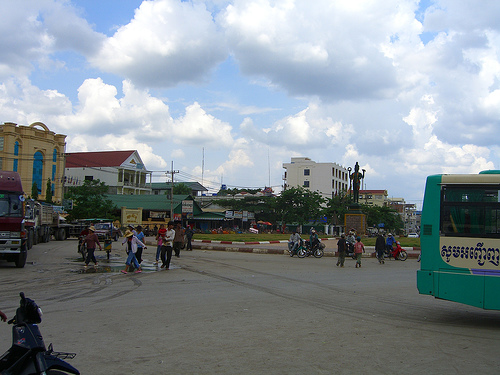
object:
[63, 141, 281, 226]
row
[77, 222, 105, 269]
people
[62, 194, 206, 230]
buildings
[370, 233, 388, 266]
people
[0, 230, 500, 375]
ground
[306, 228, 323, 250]
guy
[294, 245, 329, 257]
scooter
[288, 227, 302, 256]
guy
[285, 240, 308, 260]
scooter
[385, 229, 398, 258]
guy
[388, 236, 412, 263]
red scooter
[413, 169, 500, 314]
bus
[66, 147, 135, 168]
roof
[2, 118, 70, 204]
building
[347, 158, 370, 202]
statue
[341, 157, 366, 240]
pedestal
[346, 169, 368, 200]
two poles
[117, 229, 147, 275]
person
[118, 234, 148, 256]
white jacket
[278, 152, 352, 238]
building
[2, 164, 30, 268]
truck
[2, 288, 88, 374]
scooter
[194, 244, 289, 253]
curb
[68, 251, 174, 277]
puddle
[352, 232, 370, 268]
boy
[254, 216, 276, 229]
umbrella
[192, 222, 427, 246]
courtyard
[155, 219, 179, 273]
adult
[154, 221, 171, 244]
child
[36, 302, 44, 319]
headlight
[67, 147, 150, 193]
building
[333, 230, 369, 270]
couple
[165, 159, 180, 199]
pole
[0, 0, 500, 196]
cloud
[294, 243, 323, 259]
bike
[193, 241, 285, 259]
edge